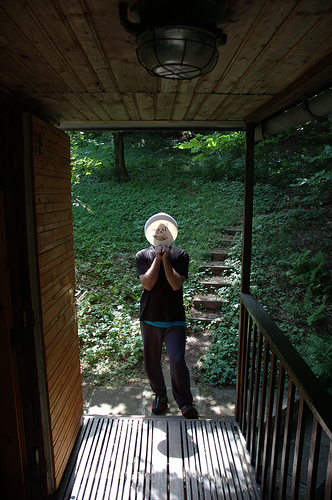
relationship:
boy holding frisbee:
[126, 214, 221, 439] [143, 213, 181, 251]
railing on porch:
[234, 291, 331, 499] [71, 265, 320, 484]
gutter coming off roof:
[249, 85, 331, 143] [29, 26, 321, 140]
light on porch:
[118, 6, 227, 77] [3, 0, 331, 499]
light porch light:
[118, 6, 227, 77] [118, 6, 227, 77]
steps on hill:
[186, 185, 245, 333] [72, 182, 330, 420]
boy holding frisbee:
[134, 211, 198, 419] [143, 213, 181, 251]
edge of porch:
[70, 124, 243, 421] [3, 0, 331, 499]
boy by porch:
[134, 211, 198, 419] [3, 0, 331, 499]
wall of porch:
[26, 109, 84, 494] [3, 0, 331, 499]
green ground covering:
[72, 182, 330, 420] [69, 132, 330, 386]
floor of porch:
[60, 416, 261, 500] [3, 0, 331, 499]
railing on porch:
[234, 291, 331, 499] [3, 0, 331, 499]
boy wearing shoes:
[134, 211, 198, 419] [149, 398, 200, 419]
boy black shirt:
[134, 211, 198, 419] [134, 246, 189, 323]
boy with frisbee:
[134, 211, 198, 419] [143, 213, 181, 251]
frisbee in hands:
[143, 213, 181, 251] [152, 243, 173, 261]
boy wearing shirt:
[134, 211, 198, 419] [134, 246, 189, 323]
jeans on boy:
[142, 323, 195, 407] [134, 211, 198, 419]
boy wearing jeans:
[134, 211, 198, 419] [142, 323, 195, 407]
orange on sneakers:
[148, 400, 188, 415] [149, 398, 200, 419]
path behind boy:
[190, 185, 293, 333] [134, 211, 198, 419]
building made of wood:
[6, 4, 327, 499] [3, 0, 331, 499]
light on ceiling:
[118, 6, 227, 77] [2, 2, 331, 129]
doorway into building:
[5, 86, 58, 500] [6, 4, 327, 499]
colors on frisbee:
[149, 218, 173, 245] [143, 213, 181, 251]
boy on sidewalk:
[134, 211, 198, 419] [85, 385, 307, 421]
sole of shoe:
[183, 410, 196, 420] [177, 402, 199, 418]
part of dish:
[279, 422, 309, 462] [283, 439, 320, 476]